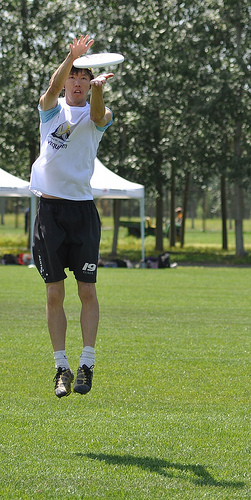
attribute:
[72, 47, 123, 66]
frisbee — white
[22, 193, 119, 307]
shorts — pair , black 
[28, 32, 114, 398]
man — Asian, jumping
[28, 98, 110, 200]
shirt — white, blue